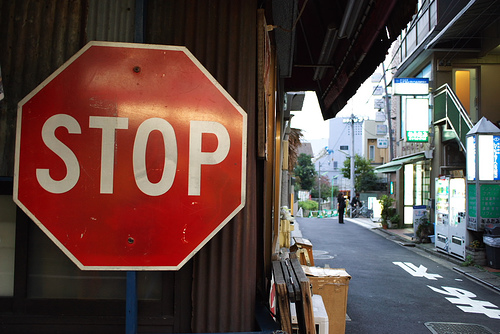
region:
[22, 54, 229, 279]
stop sign near building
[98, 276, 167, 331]
blue metal pole for stop sign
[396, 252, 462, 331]
white chinese writing on ground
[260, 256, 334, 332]
wood display holder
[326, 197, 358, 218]
woman standing in alley way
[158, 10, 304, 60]
metal colored and designed wall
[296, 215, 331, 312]
rows if cardboard boxes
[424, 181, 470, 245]
white ending machines on street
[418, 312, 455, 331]
silver man hole on ground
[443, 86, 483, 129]
green stairs attatched to building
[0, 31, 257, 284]
red stop sign against wall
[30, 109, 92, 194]
white s on sign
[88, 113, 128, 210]
white t on sign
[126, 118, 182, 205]
white o on sign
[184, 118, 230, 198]
white p on sign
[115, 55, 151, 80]
screw on stop sign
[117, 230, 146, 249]
screw on stop sign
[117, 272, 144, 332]
blue metal pole on sign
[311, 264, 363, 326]
cardboard box against wall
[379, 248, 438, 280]
white marking in road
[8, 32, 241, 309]
the stop sign is red and white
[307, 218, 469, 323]
the street has no cars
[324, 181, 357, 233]
a person is standing in the street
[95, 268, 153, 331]
the pole is blue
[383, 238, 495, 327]
white writing on the street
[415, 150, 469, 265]
two vending machines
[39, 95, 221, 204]
the letters are white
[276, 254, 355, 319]
a brown box on the street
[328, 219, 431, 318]
the street is black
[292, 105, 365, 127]
the sky is cloudy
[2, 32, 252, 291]
red and white stop sign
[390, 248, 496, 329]
two white symbols on the street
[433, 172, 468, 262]
two vending machines on the sidewalk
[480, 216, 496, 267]
black trash can with bag hanging out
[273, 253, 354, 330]
wood and boxes on side of building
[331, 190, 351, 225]
person standing at the end of street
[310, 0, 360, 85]
lights on the side of building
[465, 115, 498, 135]
pyramid is grey on top of sign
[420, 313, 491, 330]
iron cover in street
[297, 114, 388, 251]
buildings at the end of the street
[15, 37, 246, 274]
the red STOP sign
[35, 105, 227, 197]
the word STOP on the sign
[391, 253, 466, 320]
the white writing on the ground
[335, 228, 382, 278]
the dark gray pavement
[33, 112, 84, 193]
the white S on the sign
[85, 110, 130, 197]
the white T on the sign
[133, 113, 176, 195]
the white O on the sign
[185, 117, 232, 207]
the white P on the sign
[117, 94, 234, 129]
the reflection on the STOP sign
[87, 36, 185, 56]
the white rim on the STOP sign